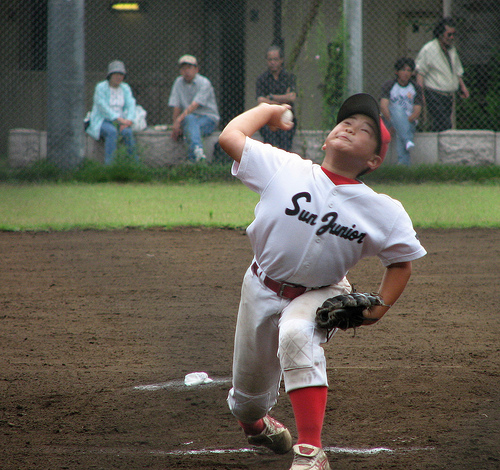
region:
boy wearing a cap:
[200, 67, 437, 467]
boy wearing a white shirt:
[210, 45, 415, 465]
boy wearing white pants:
[190, 65, 416, 465]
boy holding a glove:
[182, 60, 437, 465]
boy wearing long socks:
[202, 55, 439, 465]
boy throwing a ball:
[170, 50, 435, 465]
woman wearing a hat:
[90, 48, 148, 168]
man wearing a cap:
[167, 38, 217, 183]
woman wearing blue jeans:
[80, 48, 150, 158]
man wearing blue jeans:
[162, 46, 219, 178]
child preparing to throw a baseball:
[219, 87, 424, 469]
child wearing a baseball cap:
[216, 90, 427, 467]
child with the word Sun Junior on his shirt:
[218, 87, 427, 469]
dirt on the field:
[2, 234, 497, 469]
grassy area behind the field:
[0, 176, 496, 228]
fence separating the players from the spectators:
[2, 0, 499, 176]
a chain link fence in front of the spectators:
[0, 1, 497, 173]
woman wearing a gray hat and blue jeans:
[88, 58, 140, 165]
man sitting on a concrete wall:
[168, 52, 213, 162]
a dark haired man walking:
[415, 17, 467, 132]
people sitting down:
[51, 15, 499, 153]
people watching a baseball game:
[86, 18, 495, 148]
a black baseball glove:
[296, 256, 411, 366]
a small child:
[220, 56, 446, 323]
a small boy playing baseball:
[206, 73, 427, 454]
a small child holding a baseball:
[207, 62, 472, 247]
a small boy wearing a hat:
[249, 75, 394, 214]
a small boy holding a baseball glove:
[221, 78, 449, 348]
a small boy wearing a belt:
[201, 51, 396, 313]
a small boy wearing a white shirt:
[213, 70, 434, 320]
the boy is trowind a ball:
[212, 100, 423, 467]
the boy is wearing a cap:
[342, 90, 391, 157]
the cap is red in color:
[340, 91, 391, 158]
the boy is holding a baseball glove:
[312, 286, 379, 340]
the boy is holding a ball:
[262, 99, 297, 130]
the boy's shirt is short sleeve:
[240, 133, 425, 285]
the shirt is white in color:
[232, 133, 427, 286]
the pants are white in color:
[233, 253, 351, 418]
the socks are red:
[230, 383, 332, 455]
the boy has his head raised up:
[325, 105, 385, 170]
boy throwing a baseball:
[191, 72, 433, 467]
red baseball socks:
[219, 367, 341, 454]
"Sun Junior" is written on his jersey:
[279, 184, 383, 251]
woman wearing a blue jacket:
[73, 49, 160, 171]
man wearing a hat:
[163, 52, 230, 172]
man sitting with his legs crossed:
[364, 55, 444, 175]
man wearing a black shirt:
[256, 44, 302, 100]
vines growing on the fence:
[319, 7, 356, 141]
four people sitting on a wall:
[85, 32, 450, 172]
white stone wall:
[0, 126, 498, 175]